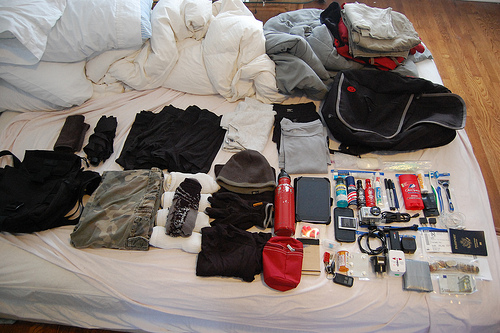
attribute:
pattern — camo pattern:
[59, 165, 162, 254]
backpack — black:
[321, 67, 467, 154]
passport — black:
[426, 207, 494, 268]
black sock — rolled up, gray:
[58, 113, 116, 159]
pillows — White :
[39, 4, 147, 39]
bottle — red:
[272, 167, 298, 235]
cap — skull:
[210, 142, 285, 204]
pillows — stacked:
[3, 0, 153, 102]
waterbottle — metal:
[271, 163, 298, 240]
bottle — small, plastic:
[334, 167, 348, 207]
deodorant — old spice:
[389, 173, 424, 213]